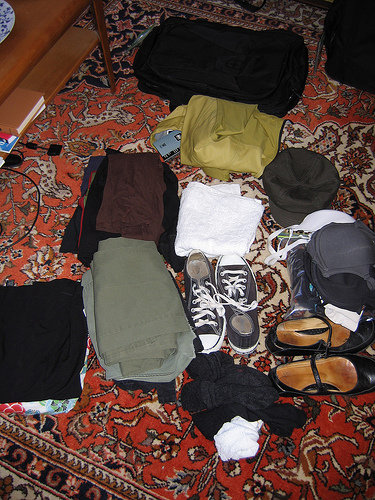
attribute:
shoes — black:
[183, 249, 260, 355]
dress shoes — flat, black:
[267, 317, 375, 396]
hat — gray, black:
[263, 147, 340, 228]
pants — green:
[89, 235, 192, 377]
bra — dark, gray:
[305, 220, 375, 291]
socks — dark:
[181, 351, 307, 459]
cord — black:
[2, 142, 62, 252]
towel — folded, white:
[174, 181, 265, 260]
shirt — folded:
[97, 152, 168, 245]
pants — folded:
[81, 237, 205, 402]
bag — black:
[132, 15, 309, 119]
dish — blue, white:
[0, 0, 17, 45]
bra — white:
[265, 211, 356, 264]